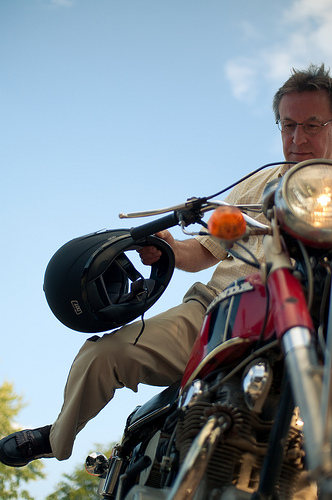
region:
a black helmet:
[40, 221, 186, 336]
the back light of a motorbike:
[79, 450, 105, 479]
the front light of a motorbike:
[207, 201, 245, 240]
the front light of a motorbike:
[274, 161, 330, 235]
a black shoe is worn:
[0, 423, 65, 474]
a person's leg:
[0, 291, 207, 472]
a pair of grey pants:
[45, 293, 207, 466]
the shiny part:
[241, 365, 269, 399]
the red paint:
[177, 270, 314, 363]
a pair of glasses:
[269, 110, 331, 134]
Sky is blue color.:
[37, 50, 132, 138]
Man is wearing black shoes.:
[5, 420, 75, 469]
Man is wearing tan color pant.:
[71, 338, 165, 378]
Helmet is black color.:
[43, 243, 174, 307]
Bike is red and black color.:
[169, 316, 292, 399]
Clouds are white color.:
[291, 6, 327, 60]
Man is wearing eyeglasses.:
[272, 114, 331, 150]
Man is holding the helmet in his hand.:
[92, 215, 217, 283]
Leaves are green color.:
[3, 389, 19, 434]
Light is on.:
[293, 171, 329, 217]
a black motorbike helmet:
[39, 226, 179, 326]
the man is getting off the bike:
[0, 125, 331, 499]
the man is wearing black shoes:
[0, 418, 71, 468]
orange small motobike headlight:
[201, 203, 251, 243]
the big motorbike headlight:
[263, 154, 331, 242]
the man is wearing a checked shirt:
[191, 159, 330, 297]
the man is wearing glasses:
[272, 64, 330, 160]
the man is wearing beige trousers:
[42, 291, 214, 463]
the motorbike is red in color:
[172, 267, 319, 389]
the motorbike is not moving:
[73, 157, 327, 493]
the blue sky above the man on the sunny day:
[2, 3, 238, 369]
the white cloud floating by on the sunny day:
[228, 4, 331, 91]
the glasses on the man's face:
[271, 116, 327, 134]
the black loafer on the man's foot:
[4, 426, 49, 467]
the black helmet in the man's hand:
[42, 224, 176, 342]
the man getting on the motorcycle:
[5, 72, 323, 474]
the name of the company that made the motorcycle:
[200, 281, 254, 311]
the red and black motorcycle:
[73, 156, 325, 498]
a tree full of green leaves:
[2, 384, 39, 497]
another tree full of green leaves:
[52, 449, 107, 499]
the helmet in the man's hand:
[41, 226, 174, 333]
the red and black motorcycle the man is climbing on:
[92, 159, 328, 495]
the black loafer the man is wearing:
[3, 429, 52, 466]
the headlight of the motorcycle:
[272, 156, 331, 242]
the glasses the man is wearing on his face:
[276, 116, 331, 136]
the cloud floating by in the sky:
[229, 2, 330, 94]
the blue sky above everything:
[1, 0, 228, 213]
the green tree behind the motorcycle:
[51, 449, 112, 499]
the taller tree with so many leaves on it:
[0, 382, 32, 498]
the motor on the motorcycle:
[176, 389, 299, 498]